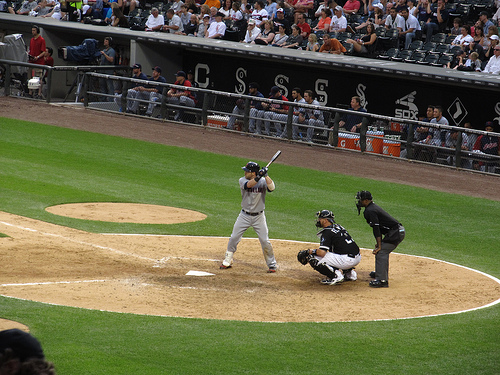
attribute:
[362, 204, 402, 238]
shirt — black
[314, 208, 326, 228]
helmet — black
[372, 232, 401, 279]
pants — gray